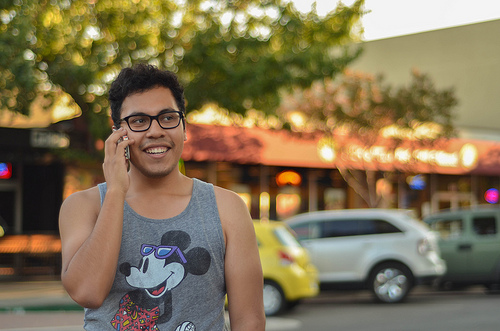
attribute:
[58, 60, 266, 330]
man — latino, talking, smiling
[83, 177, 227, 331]
tank — disney, grey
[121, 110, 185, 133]
glasses — nerdy, black, hipster, plastic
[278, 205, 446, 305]
car — white, large, new, suv, parked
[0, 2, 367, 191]
tree — blurry, large, leafy, green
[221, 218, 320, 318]
car — yellow, bright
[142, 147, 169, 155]
teeth — straight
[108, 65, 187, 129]
hair — messy, dark, brown, short, fluffy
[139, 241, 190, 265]
sunglasses — purple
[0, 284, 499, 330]
street — paved